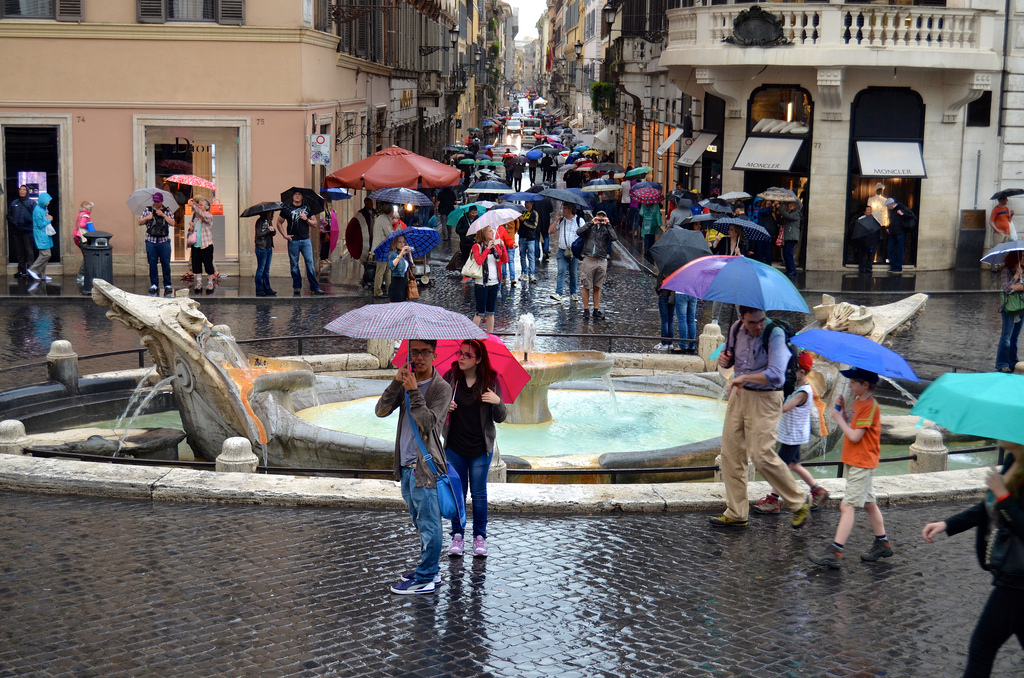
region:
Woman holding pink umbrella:
[381, 329, 528, 554]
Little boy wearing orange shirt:
[813, 361, 893, 570]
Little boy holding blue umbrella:
[794, 325, 913, 572]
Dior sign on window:
[134, 113, 248, 266]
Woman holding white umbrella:
[459, 206, 518, 333]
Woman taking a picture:
[380, 228, 422, 305]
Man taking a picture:
[577, 206, 617, 321]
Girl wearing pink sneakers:
[433, 338, 507, 558]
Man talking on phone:
[375, 335, 455, 595]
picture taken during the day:
[23, 21, 1023, 670]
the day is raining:
[40, 480, 964, 665]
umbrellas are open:
[67, 135, 968, 461]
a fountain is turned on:
[301, 333, 748, 476]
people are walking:
[484, 85, 579, 398]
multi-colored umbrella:
[669, 242, 797, 322]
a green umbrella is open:
[940, 377, 1016, 447]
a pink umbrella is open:
[486, 341, 522, 402]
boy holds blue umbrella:
[793, 325, 912, 420]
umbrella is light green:
[908, 382, 1019, 452]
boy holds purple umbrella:
[338, 274, 459, 374]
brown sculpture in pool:
[79, 255, 305, 467]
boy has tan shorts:
[842, 445, 878, 488]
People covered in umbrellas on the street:
[452, 159, 517, 233]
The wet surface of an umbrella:
[692, 264, 712, 285]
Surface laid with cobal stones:
[82, 593, 182, 674]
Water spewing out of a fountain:
[520, 315, 533, 350]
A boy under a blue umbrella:
[830, 350, 889, 361]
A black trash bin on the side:
[85, 234, 106, 276]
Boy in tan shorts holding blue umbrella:
[784, 320, 917, 570]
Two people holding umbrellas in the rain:
[319, 297, 536, 596]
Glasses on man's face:
[408, 345, 434, 358]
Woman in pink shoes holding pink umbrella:
[388, 328, 534, 559]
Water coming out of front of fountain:
[106, 358, 201, 460]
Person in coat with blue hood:
[28, 186, 54, 282]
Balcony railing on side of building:
[656, 4, 1011, 72]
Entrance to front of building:
[843, 80, 930, 281]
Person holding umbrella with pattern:
[163, 168, 220, 296]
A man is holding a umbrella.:
[640, 243, 796, 311]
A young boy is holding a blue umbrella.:
[789, 318, 908, 388]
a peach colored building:
[8, 4, 375, 240]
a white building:
[572, 0, 1002, 259]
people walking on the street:
[35, 79, 1004, 561]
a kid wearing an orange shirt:
[827, 364, 886, 548]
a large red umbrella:
[347, 136, 459, 184]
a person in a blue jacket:
[27, 189, 66, 267]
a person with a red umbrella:
[186, 176, 225, 282]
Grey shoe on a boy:
[799, 541, 847, 577]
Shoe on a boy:
[857, 535, 897, 565]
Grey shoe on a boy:
[859, 535, 899, 568]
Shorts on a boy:
[838, 458, 878, 510]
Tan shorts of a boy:
[837, 452, 882, 516]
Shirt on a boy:
[843, 386, 888, 476]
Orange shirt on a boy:
[836, 398, 884, 476]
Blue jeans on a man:
[395, 455, 450, 592]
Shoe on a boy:
[805, 541, 847, 570]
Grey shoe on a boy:
[802, 535, 845, 573]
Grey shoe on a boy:
[860, 530, 899, 563]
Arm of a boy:
[830, 401, 868, 450]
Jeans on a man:
[394, 458, 449, 583]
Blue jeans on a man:
[395, 459, 456, 581]